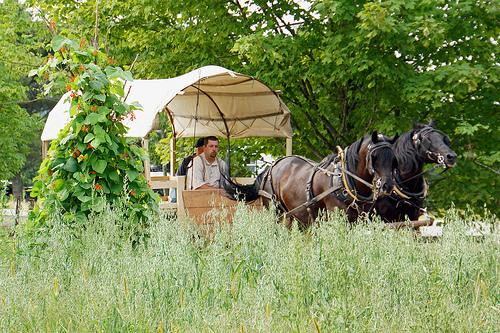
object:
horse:
[220, 128, 399, 230]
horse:
[375, 119, 459, 221]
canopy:
[41, 64, 295, 147]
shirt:
[188, 152, 231, 189]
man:
[170, 135, 208, 202]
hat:
[193, 136, 206, 148]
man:
[185, 136, 228, 189]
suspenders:
[199, 154, 223, 185]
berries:
[94, 182, 103, 191]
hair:
[346, 137, 363, 175]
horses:
[221, 121, 459, 233]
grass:
[1, 233, 495, 333]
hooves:
[272, 252, 421, 263]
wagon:
[40, 64, 457, 225]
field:
[2, 200, 500, 333]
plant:
[29, 22, 160, 236]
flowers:
[77, 37, 87, 51]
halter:
[367, 139, 395, 167]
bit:
[371, 176, 383, 193]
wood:
[285, 136, 292, 157]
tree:
[231, 1, 426, 162]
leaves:
[358, 4, 397, 33]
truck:
[420, 212, 494, 241]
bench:
[175, 186, 266, 222]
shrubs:
[431, 167, 500, 217]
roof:
[41, 64, 296, 143]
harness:
[330, 153, 381, 214]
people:
[171, 137, 228, 198]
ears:
[369, 129, 402, 146]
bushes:
[2, 141, 499, 331]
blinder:
[359, 141, 400, 174]